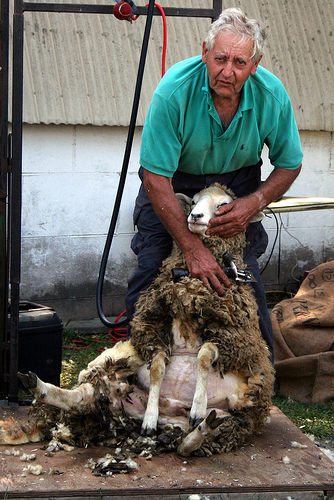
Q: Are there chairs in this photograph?
A: No, there are no chairs.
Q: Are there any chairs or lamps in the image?
A: No, there are no chairs or lamps.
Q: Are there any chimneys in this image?
A: No, there are no chimneys.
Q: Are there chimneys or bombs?
A: No, there are no chimneys or bombs.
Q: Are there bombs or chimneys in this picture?
A: No, there are no chimneys or bombs.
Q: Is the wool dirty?
A: Yes, the wool is dirty.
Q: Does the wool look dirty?
A: Yes, the wool is dirty.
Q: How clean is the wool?
A: The wool is dirty.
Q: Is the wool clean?
A: No, the wool is dirty.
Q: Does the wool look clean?
A: No, the wool is dirty.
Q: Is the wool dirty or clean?
A: The wool is dirty.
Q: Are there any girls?
A: No, there are no girls.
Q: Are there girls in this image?
A: No, there are no girls.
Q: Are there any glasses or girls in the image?
A: No, there are no girls or glasses.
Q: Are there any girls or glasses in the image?
A: No, there are no girls or glasses.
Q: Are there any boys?
A: No, there are no boys.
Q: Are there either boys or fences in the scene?
A: No, there are no boys or fences.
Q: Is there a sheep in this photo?
A: Yes, there is a sheep.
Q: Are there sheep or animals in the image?
A: Yes, there is a sheep.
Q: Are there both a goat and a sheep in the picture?
A: No, there is a sheep but no goats.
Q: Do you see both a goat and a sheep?
A: No, there is a sheep but no goats.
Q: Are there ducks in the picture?
A: No, there are no ducks.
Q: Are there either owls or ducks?
A: No, there are no ducks or owls.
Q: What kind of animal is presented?
A: The animal is a sheep.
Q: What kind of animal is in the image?
A: The animal is a sheep.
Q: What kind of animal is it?
A: The animal is a sheep.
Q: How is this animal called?
A: This is a sheep.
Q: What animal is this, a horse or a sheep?
A: This is a sheep.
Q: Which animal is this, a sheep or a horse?
A: This is a sheep.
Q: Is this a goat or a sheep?
A: This is a sheep.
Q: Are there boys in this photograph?
A: No, there are no boys.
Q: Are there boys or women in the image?
A: No, there are no boys or women.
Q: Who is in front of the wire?
A: The man is in front of the wire.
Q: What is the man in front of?
A: The man is in front of the wire.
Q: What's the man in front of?
A: The man is in front of the wire.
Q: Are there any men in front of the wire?
A: Yes, there is a man in front of the wire.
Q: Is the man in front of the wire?
A: Yes, the man is in front of the wire.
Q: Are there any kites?
A: No, there are no kites.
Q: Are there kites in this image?
A: No, there are no kites.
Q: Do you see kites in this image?
A: No, there are no kites.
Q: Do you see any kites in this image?
A: No, there are no kites.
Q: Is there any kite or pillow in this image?
A: No, there are no kites or pillows.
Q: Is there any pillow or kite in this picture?
A: No, there are no kites or pillows.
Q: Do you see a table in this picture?
A: Yes, there is a table.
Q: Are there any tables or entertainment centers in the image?
A: Yes, there is a table.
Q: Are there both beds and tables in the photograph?
A: No, there is a table but no beds.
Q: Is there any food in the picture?
A: No, there is no food.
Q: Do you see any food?
A: No, there is no food.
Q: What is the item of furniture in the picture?
A: The piece of furniture is a table.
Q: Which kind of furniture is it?
A: The piece of furniture is a table.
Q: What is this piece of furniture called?
A: This is a table.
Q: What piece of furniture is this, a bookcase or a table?
A: This is a table.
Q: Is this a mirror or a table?
A: This is a table.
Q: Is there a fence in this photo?
A: No, there are no fences.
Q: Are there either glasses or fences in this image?
A: No, there are no fences or glasses.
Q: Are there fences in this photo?
A: No, there are no fences.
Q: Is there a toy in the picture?
A: No, there are no toys.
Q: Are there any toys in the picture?
A: No, there are no toys.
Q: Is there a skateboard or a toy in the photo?
A: No, there are no toys or skateboards.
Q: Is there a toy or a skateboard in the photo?
A: No, there are no toys or skateboards.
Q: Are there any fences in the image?
A: No, there are no fences.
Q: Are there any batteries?
A: No, there are no batteries.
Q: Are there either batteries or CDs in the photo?
A: No, there are no batteries or cds.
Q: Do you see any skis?
A: No, there are no skis.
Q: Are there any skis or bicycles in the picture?
A: No, there are no skis or bicycles.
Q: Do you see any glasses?
A: No, there are no glasses.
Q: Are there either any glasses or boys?
A: No, there are no glasses or boys.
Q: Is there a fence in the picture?
A: No, there are no fences.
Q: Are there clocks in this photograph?
A: No, there are no clocks.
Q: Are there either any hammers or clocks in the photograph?
A: No, there are no clocks or hammers.